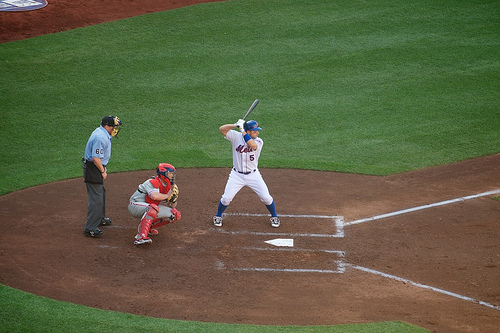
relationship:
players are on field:
[211, 119, 281, 228] [1, 0, 498, 332]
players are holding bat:
[211, 119, 281, 228] [236, 99, 265, 126]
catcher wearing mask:
[128, 163, 183, 246] [158, 164, 175, 183]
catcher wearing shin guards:
[128, 163, 183, 246] [135, 203, 159, 239]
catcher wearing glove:
[128, 163, 183, 246] [168, 183, 179, 202]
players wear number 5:
[211, 119, 281, 228] [250, 154, 256, 164]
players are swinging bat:
[211, 119, 281, 228] [236, 99, 265, 126]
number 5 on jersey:
[250, 154, 256, 164] [223, 130, 262, 174]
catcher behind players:
[128, 163, 183, 246] [211, 119, 281, 228]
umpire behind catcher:
[80, 113, 123, 239] [128, 163, 183, 246]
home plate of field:
[264, 237, 295, 250] [1, 0, 498, 332]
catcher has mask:
[128, 163, 183, 246] [158, 164, 175, 183]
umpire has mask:
[80, 113, 123, 239] [112, 115, 122, 137]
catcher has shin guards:
[128, 163, 183, 246] [135, 203, 159, 239]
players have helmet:
[211, 119, 281, 228] [243, 120, 262, 130]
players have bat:
[211, 119, 281, 228] [236, 99, 265, 126]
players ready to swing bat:
[211, 119, 281, 228] [236, 99, 265, 126]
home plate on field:
[264, 237, 295, 250] [1, 0, 498, 332]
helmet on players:
[243, 120, 262, 130] [211, 119, 281, 228]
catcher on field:
[128, 163, 183, 246] [1, 0, 498, 332]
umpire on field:
[80, 113, 123, 239] [1, 0, 498, 332]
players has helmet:
[211, 119, 281, 228] [243, 120, 262, 130]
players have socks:
[211, 119, 281, 228] [265, 201, 278, 216]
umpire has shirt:
[80, 113, 123, 239] [81, 125, 112, 167]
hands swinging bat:
[235, 119, 245, 133] [236, 99, 265, 126]